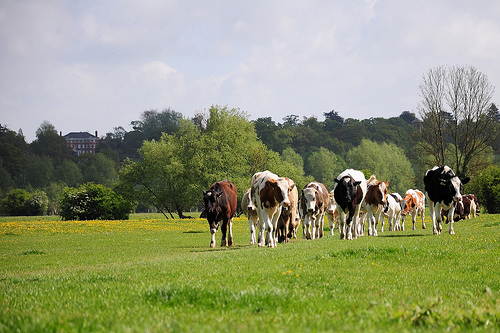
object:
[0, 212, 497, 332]
grass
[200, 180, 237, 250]
cow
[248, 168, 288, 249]
cow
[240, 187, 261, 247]
cow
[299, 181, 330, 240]
cow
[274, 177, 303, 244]
cow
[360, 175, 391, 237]
cow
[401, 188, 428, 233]
cow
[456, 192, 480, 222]
cow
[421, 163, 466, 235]
cow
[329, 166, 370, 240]
cow